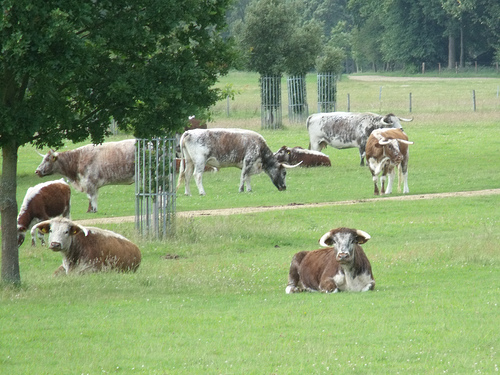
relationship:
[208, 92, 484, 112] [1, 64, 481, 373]
fence in field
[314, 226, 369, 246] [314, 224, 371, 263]
horns on head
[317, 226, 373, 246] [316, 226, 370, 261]
horns on head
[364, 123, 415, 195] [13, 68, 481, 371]
animal in grass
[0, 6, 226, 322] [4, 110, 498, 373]
tree in field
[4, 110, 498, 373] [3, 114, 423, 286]
field has bulls